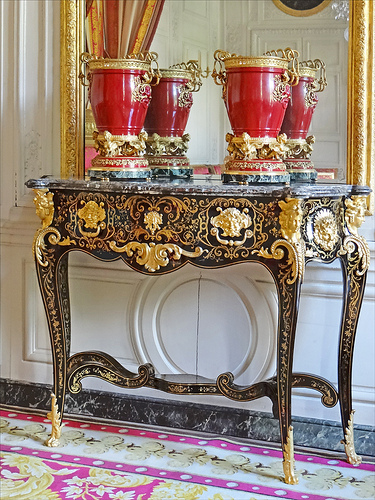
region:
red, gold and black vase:
[212, 47, 297, 182]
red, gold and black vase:
[80, 50, 157, 179]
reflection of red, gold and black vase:
[159, 59, 198, 180]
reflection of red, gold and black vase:
[302, 60, 318, 187]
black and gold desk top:
[26, 180, 369, 261]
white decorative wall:
[82, 271, 267, 352]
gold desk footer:
[278, 430, 299, 483]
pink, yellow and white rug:
[90, 426, 198, 498]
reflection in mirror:
[172, 8, 270, 42]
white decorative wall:
[16, 11, 52, 167]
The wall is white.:
[5, 213, 374, 433]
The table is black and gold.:
[23, 168, 363, 485]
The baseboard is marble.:
[2, 369, 374, 461]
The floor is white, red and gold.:
[2, 400, 373, 498]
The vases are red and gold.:
[207, 40, 300, 188]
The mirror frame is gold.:
[51, 1, 91, 180]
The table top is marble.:
[25, 163, 374, 208]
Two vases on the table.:
[69, 40, 312, 196]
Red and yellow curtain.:
[79, 1, 169, 76]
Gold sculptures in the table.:
[26, 179, 371, 265]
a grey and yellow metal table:
[31, 183, 366, 481]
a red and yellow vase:
[74, 57, 155, 181]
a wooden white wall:
[0, 5, 56, 171]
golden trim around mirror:
[347, 0, 370, 182]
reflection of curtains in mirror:
[84, 1, 173, 49]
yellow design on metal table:
[64, 200, 270, 249]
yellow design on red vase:
[216, 134, 293, 159]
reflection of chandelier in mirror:
[332, 0, 349, 25]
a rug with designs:
[75, 424, 207, 496]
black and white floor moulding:
[109, 396, 182, 422]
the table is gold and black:
[27, 175, 366, 479]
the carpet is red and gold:
[1, 404, 372, 497]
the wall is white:
[0, 6, 373, 428]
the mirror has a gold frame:
[50, 0, 368, 213]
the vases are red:
[83, 55, 323, 187]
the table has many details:
[30, 176, 372, 474]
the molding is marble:
[1, 377, 373, 455]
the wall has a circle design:
[136, 266, 281, 405]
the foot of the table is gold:
[46, 399, 362, 485]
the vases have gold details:
[82, 50, 324, 181]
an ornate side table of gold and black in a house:
[19, 168, 374, 483]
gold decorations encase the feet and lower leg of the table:
[277, 422, 298, 484]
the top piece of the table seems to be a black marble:
[19, 174, 370, 199]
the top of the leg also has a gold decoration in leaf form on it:
[264, 239, 306, 287]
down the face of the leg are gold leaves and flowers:
[265, 260, 303, 424]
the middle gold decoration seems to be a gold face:
[141, 207, 166, 233]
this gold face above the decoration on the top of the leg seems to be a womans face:
[278, 199, 306, 239]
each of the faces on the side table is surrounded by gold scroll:
[302, 199, 346, 256]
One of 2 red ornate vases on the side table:
[74, 51, 160, 177]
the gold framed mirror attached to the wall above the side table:
[50, 0, 373, 180]